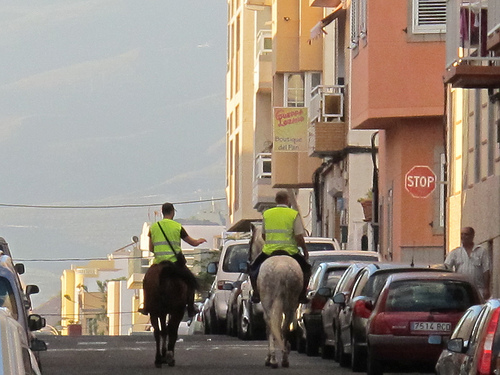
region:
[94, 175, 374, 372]
two horsemen are riding down an urban street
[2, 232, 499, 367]
cars are parked on both sides of the street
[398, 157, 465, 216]
an octagon stop sign is on a building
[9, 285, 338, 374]
the road goes downhill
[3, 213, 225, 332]
mountains are in the distance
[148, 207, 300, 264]
the riders are wearing bright vests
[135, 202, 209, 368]
the man is on a black horse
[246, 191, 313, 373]
the man is on a gray horse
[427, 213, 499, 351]
a man is standing behind a parked car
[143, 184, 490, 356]
the man is looking at the horse riders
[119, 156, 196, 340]
a man riding the horse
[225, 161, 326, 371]
a man riding the horse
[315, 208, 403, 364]
cars are parked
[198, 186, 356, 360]
cars are parked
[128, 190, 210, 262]
the vest is neon green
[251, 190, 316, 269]
the vest is neon green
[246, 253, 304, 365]
grey and white horse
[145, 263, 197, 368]
brown and black horse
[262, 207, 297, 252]
green and grey vest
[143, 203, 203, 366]
man riding on horse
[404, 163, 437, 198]
red and white stop sign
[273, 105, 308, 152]
store sign on building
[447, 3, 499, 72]
grey railing on patio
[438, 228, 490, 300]
man wearing button down shirt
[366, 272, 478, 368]
red car parked by curb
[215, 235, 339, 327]
white van parked at curb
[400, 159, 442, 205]
stop sign mounted on building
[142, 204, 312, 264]
fluorescent green vests with reflective stripe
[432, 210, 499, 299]
pedestrian watches mounted patrol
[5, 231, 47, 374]
a line of sideview mirrors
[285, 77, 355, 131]
balacony on second floor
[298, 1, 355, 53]
awning over balacony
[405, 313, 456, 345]
european license plates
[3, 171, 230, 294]
utility lines over the road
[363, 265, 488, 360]
red hatchback in park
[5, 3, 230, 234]
blue sky with light clouds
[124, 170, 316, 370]
two men riding horses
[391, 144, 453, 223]
a red and white street sign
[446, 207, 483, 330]
a man walking on a side walk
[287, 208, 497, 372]
a row of cars parked on the side of a street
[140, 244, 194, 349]
a brown horse with a black tail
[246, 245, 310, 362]
a white and grey horse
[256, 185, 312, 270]
a man wearing a yellow safety vest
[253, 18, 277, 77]
a balcony on a building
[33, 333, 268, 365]
white lines painted on a street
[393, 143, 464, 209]
a stop sign attached to a building